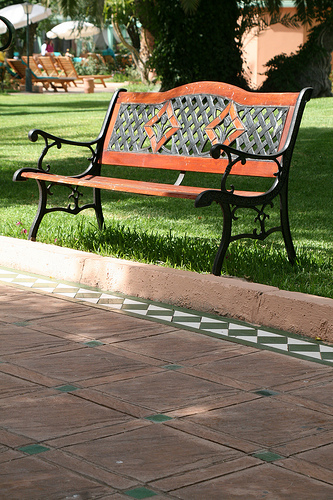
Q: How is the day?
A: Sunny.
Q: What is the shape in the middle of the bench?
A: Diamond.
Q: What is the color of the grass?
A: Green.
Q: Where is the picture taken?
A: A park.